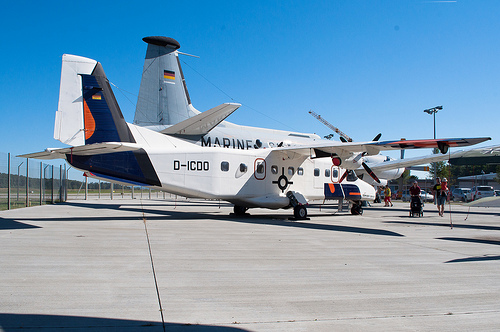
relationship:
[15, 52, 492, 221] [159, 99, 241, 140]
plane has wing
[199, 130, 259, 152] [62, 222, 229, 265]
word on side of plane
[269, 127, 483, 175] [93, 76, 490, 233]
wing on plane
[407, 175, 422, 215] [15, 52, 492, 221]
people near plane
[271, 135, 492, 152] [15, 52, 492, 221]
wing of plane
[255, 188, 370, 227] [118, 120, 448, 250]
wheel of plane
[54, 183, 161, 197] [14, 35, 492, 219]
fencing behind planes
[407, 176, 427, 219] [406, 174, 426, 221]
woman pushing stroller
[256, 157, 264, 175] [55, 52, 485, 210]
window on plane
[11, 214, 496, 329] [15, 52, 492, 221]
ground under plane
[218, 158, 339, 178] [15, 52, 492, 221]
windows on plane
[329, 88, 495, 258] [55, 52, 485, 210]
plane wing of plane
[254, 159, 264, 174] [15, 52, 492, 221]
window of plane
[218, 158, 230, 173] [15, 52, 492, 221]
window on plane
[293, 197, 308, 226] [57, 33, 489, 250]
wheel of plane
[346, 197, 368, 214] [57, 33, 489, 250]
wheel of plane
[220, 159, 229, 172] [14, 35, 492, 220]
passenger window on white plane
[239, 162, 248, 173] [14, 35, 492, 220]
passenger window on white plane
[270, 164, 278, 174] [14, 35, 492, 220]
passenger window on white plane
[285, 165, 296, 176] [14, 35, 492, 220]
passenger window on white plane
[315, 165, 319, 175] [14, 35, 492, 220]
passenger window on white plane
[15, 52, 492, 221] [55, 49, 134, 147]
plane has wing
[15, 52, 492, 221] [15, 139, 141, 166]
plane has wing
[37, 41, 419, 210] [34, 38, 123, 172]
plane has tail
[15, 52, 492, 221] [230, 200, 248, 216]
plane has wheel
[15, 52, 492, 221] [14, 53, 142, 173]
plane has tail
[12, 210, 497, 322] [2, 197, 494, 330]
concrete on ground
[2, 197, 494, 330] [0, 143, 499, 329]
ground in airport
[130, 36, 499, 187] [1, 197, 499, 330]
gray plane sitting in parking lot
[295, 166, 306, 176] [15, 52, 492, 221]
window on plane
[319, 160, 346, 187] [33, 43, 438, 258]
window on plane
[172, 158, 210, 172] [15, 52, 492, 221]
figures on plane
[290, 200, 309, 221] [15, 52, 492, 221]
wheel on plane